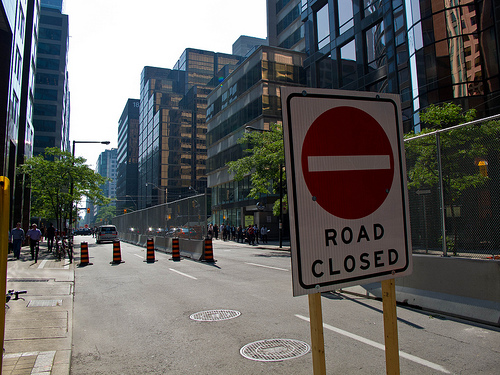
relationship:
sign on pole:
[277, 82, 417, 299] [381, 273, 402, 374]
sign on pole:
[277, 82, 417, 299] [304, 293, 329, 373]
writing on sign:
[312, 218, 400, 284] [277, 82, 417, 299]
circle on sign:
[299, 104, 397, 220] [277, 82, 417, 299]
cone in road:
[79, 238, 89, 265] [70, 233, 498, 373]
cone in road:
[109, 238, 125, 265] [70, 233, 498, 373]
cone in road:
[144, 231, 158, 262] [70, 233, 498, 373]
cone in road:
[171, 233, 181, 262] [70, 233, 498, 373]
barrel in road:
[197, 233, 221, 263] [70, 233, 498, 373]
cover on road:
[193, 308, 238, 329] [70, 233, 498, 373]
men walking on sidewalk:
[6, 218, 26, 261] [2, 234, 77, 370]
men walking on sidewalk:
[24, 220, 43, 260] [2, 234, 77, 370]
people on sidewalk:
[255, 223, 271, 239] [176, 222, 497, 268]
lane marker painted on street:
[167, 265, 198, 281] [53, 219, 497, 372]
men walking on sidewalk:
[6, 218, 26, 261] [4, 237, 83, 369]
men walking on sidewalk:
[24, 220, 43, 260] [4, 237, 83, 369]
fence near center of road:
[105, 189, 215, 263] [70, 233, 498, 373]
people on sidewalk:
[214, 219, 231, 246] [143, 218, 498, 272]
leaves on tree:
[51, 163, 58, 170] [15, 138, 121, 258]